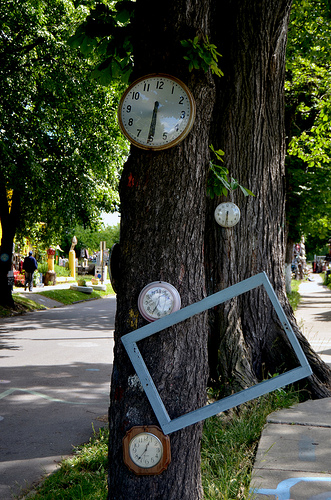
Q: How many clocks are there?
A: 4.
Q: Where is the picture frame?
A: Attached to the tree.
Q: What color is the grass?
A: Green.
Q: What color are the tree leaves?
A: Green.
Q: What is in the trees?
A: Clock and frame.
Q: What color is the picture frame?
A: Blue.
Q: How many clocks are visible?
A: Four.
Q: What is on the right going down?
A: Sidewalk.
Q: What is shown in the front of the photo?
A: Tree trunk.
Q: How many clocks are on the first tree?
A: Three.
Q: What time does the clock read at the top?
A: 6:30.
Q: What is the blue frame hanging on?
A: Tree trunk.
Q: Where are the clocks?
A: On the tree trunks.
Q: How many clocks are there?
A: 4.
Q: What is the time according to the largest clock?
A: 6:30.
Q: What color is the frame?
A: Blue.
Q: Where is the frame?
A: Attached to the tree.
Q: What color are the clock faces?
A: White.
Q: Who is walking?
A: Person with blue jacket.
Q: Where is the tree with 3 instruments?
A: On the nearest tree.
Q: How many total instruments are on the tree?
A: 4.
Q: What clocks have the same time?
A: Top clock of three and the single clock.